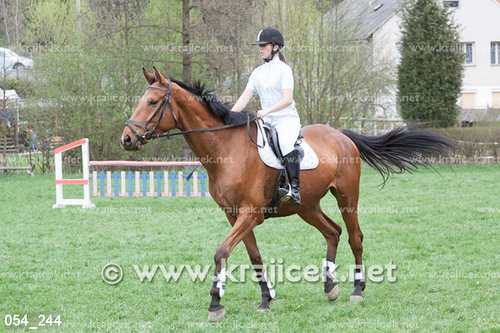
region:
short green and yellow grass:
[36, 241, 100, 282]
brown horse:
[117, 82, 198, 152]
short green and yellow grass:
[76, 268, 110, 292]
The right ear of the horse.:
[150, 61, 170, 86]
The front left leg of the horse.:
[227, 204, 275, 306]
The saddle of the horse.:
[257, 125, 319, 170]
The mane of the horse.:
[171, 74, 245, 126]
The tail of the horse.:
[345, 127, 462, 181]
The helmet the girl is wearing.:
[252, 25, 282, 47]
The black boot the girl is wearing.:
[274, 149, 308, 204]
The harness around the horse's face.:
[117, 101, 167, 142]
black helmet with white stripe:
[254, 27, 288, 52]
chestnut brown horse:
[111, 66, 461, 316]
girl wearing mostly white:
[221, 24, 309, 210]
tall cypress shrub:
[392, 0, 467, 132]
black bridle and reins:
[117, 81, 270, 145]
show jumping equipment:
[43, 134, 226, 214]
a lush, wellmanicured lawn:
[5, 154, 499, 330]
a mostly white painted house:
[314, 4, 499, 137]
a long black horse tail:
[345, 124, 477, 181]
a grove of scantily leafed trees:
[12, 4, 399, 159]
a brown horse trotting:
[121, 57, 472, 332]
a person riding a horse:
[209, 18, 331, 211]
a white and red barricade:
[42, 128, 114, 221]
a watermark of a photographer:
[80, 248, 431, 312]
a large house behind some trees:
[308, 8, 495, 110]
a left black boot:
[272, 143, 304, 216]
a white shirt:
[241, 59, 301, 120]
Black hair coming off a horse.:
[340, 124, 459, 188]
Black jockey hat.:
[252, 27, 284, 49]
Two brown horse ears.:
[139, 65, 166, 83]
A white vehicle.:
[0, 45, 35, 70]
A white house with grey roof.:
[305, 0, 499, 119]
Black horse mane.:
[168, 76, 257, 125]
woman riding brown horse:
[115, 24, 372, 326]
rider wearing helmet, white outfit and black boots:
[234, 20, 303, 207]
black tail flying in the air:
[319, 115, 466, 191]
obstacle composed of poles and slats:
[55, 130, 217, 212]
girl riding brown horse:
[116, 24, 463, 327]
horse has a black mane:
[119, 62, 466, 325]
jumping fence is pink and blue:
[54, 134, 213, 209]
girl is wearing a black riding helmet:
[227, 25, 307, 207]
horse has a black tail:
[119, 61, 466, 326]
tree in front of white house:
[311, 1, 498, 126]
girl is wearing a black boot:
[229, 28, 304, 204]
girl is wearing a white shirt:
[231, 26, 303, 206]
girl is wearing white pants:
[119, 21, 303, 205]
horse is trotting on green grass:
[1, 64, 498, 331]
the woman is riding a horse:
[237, 25, 307, 206]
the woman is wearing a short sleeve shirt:
[249, 53, 299, 119]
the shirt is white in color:
[246, 53, 294, 115]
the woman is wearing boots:
[277, 150, 302, 206]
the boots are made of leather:
[277, 148, 305, 208]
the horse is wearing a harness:
[126, 74, 262, 147]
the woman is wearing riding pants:
[257, 110, 299, 162]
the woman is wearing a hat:
[252, 26, 284, 45]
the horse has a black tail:
[334, 120, 459, 187]